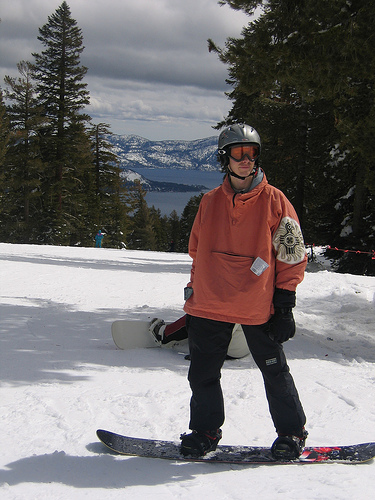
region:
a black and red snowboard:
[94, 428, 371, 460]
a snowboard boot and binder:
[177, 427, 218, 453]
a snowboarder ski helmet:
[216, 121, 256, 148]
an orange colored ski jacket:
[181, 167, 302, 320]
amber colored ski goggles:
[225, 142, 256, 157]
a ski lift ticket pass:
[248, 255, 264, 273]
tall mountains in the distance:
[97, 127, 217, 164]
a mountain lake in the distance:
[131, 161, 209, 214]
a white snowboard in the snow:
[110, 317, 183, 348]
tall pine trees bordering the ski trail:
[1, 0, 95, 246]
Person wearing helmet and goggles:
[213, 121, 276, 191]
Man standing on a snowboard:
[97, 123, 371, 473]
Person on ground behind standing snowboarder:
[106, 257, 273, 374]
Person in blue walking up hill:
[86, 220, 120, 254]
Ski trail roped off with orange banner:
[307, 236, 373, 272]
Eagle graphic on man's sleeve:
[269, 216, 309, 273]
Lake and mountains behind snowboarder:
[116, 126, 242, 241]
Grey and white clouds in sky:
[89, 10, 242, 130]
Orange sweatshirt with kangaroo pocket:
[181, 171, 298, 317]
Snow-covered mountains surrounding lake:
[103, 124, 217, 180]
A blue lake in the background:
[77, 140, 267, 235]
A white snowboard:
[90, 302, 203, 356]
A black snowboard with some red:
[92, 417, 371, 467]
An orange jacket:
[173, 169, 308, 333]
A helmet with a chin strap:
[212, 118, 267, 189]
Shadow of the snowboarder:
[1, 446, 267, 491]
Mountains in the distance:
[90, 122, 243, 192]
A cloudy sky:
[1, 3, 265, 128]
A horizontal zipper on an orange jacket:
[205, 242, 260, 267]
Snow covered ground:
[1, 239, 371, 496]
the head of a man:
[215, 118, 266, 183]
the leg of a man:
[182, 320, 231, 433]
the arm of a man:
[267, 192, 309, 293]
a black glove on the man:
[263, 285, 303, 347]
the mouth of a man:
[237, 163, 252, 169]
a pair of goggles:
[225, 141, 264, 163]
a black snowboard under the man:
[92, 425, 374, 465]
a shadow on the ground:
[0, 447, 261, 491]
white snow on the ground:
[0, 241, 373, 499]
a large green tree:
[16, 0, 94, 245]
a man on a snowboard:
[67, 75, 329, 458]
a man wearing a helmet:
[74, 62, 339, 428]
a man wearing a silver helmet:
[129, 94, 313, 331]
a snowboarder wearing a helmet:
[129, 64, 367, 305]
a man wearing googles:
[171, 88, 326, 302]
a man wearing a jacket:
[171, 87, 332, 384]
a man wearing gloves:
[123, 110, 329, 412]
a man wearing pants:
[108, 79, 359, 488]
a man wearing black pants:
[106, 117, 340, 498]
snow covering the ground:
[26, 248, 111, 327]